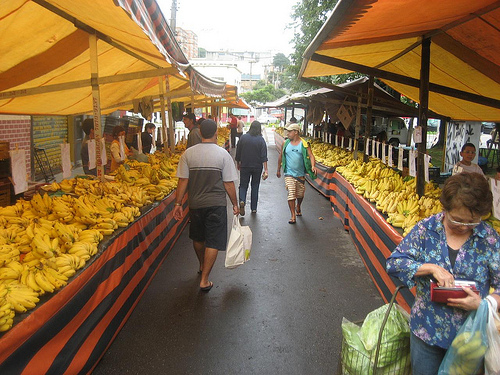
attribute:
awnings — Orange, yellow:
[0, 2, 491, 116]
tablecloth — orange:
[33, 244, 123, 373]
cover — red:
[344, 206, 387, 275]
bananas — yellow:
[2, 149, 176, 327]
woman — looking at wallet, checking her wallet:
[382, 170, 498, 373]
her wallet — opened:
[429, 276, 480, 310]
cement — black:
[112, 147, 381, 369]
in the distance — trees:
[158, 1, 337, 120]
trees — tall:
[243, 1, 363, 106]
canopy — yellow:
[1, 1, 153, 109]